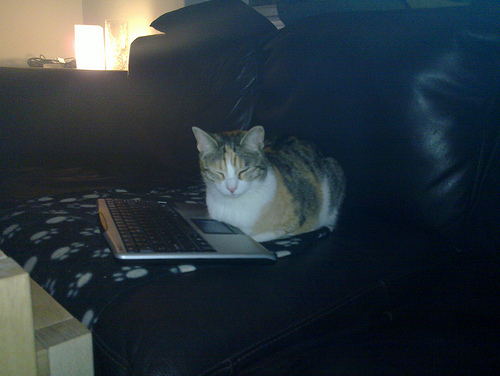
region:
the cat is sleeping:
[190, 128, 341, 232]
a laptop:
[104, 191, 214, 270]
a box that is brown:
[32, 305, 78, 360]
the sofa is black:
[300, 45, 435, 130]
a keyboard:
[118, 195, 194, 263]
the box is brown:
[0, 290, 65, 357]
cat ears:
[240, 132, 271, 162]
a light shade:
[70, 22, 133, 74]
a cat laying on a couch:
[191, 117, 348, 253]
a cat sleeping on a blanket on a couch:
[182, 130, 352, 274]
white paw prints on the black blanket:
[28, 196, 100, 296]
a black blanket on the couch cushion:
[8, 178, 118, 317]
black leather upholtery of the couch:
[182, 300, 280, 344]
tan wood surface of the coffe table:
[0, 304, 93, 367]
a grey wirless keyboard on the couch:
[88, 178, 261, 261]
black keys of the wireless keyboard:
[118, 198, 200, 253]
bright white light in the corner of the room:
[66, 15, 118, 71]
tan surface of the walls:
[13, 3, 53, 48]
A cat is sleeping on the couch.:
[190, 123, 346, 233]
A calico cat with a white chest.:
[190, 123, 344, 235]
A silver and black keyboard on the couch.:
[93, 193, 280, 263]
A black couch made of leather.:
[3, 10, 494, 365]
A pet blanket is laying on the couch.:
[7, 176, 353, 321]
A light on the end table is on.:
[72, 17, 107, 70]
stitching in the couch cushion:
[254, 256, 446, 367]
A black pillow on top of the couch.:
[148, 0, 278, 32]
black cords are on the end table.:
[26, 53, 77, 66]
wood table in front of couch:
[0, 251, 95, 372]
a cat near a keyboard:
[108, 90, 390, 295]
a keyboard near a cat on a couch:
[87, 107, 370, 289]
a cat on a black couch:
[87, 8, 429, 308]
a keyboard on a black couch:
[100, 176, 287, 298]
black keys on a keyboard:
[123, 185, 216, 259]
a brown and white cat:
[192, 84, 443, 246]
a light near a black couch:
[40, 0, 162, 123]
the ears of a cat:
[185, 99, 369, 171]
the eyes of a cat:
[205, 158, 272, 192]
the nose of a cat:
[217, 180, 247, 204]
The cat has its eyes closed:
[186, 110, 352, 250]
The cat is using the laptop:
[90, 117, 351, 265]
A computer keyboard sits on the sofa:
[86, 165, 276, 279]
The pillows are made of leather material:
[127, 24, 498, 176]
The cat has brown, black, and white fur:
[190, 115, 352, 245]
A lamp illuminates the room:
[67, 16, 162, 74]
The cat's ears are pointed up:
[184, 120, 272, 157]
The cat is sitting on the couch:
[81, 113, 386, 308]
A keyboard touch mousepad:
[187, 209, 242, 241]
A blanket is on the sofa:
[4, 171, 340, 309]